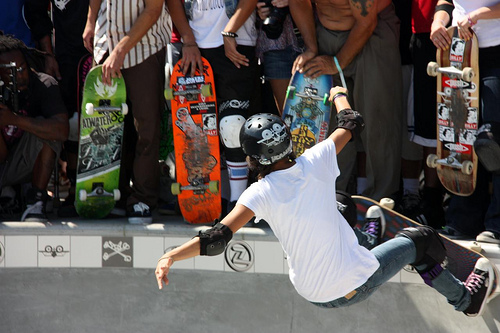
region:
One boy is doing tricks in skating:
[219, 120, 486, 318]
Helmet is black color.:
[228, 114, 300, 173]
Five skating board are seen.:
[76, 66, 498, 279]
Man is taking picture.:
[1, 63, 53, 225]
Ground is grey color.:
[33, 275, 138, 312]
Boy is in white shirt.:
[223, 109, 374, 294]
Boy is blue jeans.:
[319, 232, 477, 312]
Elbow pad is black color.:
[195, 218, 232, 253]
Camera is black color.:
[0, 64, 24, 115]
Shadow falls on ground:
[8, 216, 218, 239]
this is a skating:
[423, 23, 488, 195]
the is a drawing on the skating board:
[171, 101, 218, 206]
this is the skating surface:
[11, 270, 359, 330]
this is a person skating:
[203, 116, 487, 317]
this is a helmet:
[227, 115, 303, 175]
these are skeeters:
[3, 2, 490, 219]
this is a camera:
[1, 64, 26, 120]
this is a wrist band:
[218, 22, 233, 42]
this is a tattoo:
[341, 0, 379, 29]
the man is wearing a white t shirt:
[230, 140, 360, 297]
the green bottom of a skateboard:
[78, 62, 126, 214]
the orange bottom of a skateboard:
[166, 56, 231, 223]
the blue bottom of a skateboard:
[277, 57, 338, 162]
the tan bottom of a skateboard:
[425, 21, 486, 194]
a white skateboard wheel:
[425, 152, 437, 167]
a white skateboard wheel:
[459, 158, 476, 178]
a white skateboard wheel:
[75, 187, 90, 203]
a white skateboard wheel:
[112, 187, 122, 200]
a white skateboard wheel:
[85, 101, 97, 116]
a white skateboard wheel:
[118, 101, 133, 116]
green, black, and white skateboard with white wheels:
[75, 61, 128, 220]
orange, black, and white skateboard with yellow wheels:
[164, 53, 227, 230]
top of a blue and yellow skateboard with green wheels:
[279, 54, 336, 162]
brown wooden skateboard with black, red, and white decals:
[421, 23, 486, 200]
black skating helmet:
[238, 110, 297, 162]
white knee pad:
[215, 112, 252, 151]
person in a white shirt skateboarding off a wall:
[145, 80, 499, 331]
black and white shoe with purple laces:
[360, 202, 390, 245]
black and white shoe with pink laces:
[462, 251, 497, 316]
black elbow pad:
[193, 219, 239, 262]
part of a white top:
[303, 211, 371, 251]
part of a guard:
[417, 232, 449, 259]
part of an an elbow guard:
[206, 241, 229, 263]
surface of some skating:
[208, 296, 253, 328]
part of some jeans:
[376, 247, 408, 269]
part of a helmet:
[249, 132, 284, 164]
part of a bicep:
[328, 128, 347, 156]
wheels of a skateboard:
[165, 172, 215, 219]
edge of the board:
[443, 182, 470, 204]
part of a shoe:
[465, 248, 494, 292]